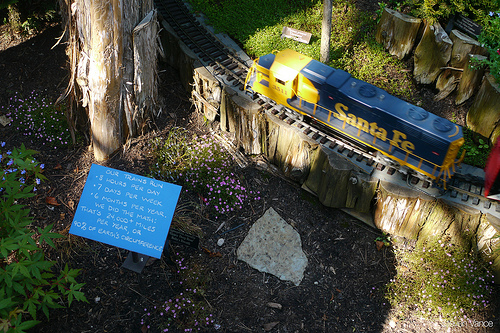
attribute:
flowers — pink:
[138, 165, 244, 329]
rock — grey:
[235, 200, 315, 286]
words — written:
[70, 165, 170, 253]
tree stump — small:
[50, 0, 169, 164]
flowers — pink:
[382, 232, 497, 304]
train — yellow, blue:
[243, 41, 467, 178]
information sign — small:
[280, 19, 312, 43]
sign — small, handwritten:
[58, 157, 208, 279]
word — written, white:
[102, 165, 125, 180]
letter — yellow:
[329, 97, 351, 125]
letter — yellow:
[335, 98, 347, 128]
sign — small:
[276, 24, 318, 46]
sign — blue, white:
[54, 155, 209, 259]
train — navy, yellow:
[218, 32, 470, 192]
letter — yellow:
[337, 109, 450, 165]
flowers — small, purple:
[182, 134, 254, 217]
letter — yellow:
[388, 127, 406, 149]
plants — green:
[4, 149, 96, 331]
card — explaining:
[453, 11, 487, 44]